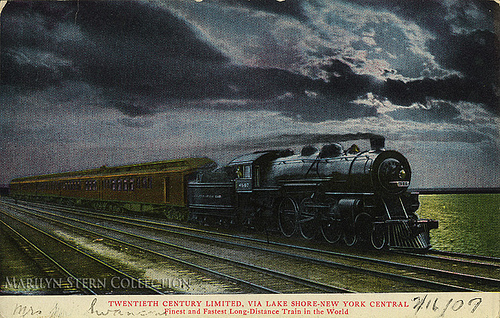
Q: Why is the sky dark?
A: Clouds.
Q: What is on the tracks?
A: The train.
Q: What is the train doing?
A: Moving.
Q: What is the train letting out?
A: Smoke.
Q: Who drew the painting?
A: A person.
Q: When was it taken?
A: 2/16/09.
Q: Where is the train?
A: On the tracks.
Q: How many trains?
A: 1.